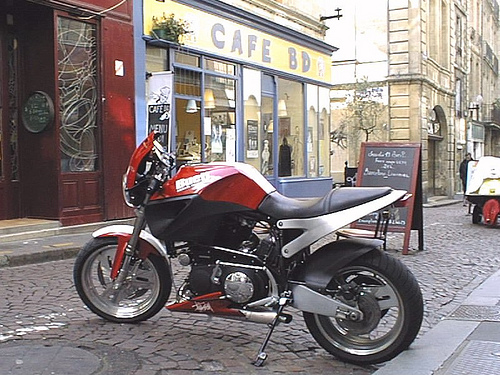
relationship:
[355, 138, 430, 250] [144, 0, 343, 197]
sign in front of cafe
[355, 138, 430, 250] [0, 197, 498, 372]
sign in middle of road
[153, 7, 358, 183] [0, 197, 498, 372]
cafe on side of road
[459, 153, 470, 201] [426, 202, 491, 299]
person walking down road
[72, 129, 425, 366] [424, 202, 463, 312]
motorcycle on street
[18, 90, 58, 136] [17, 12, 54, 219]
sign on wall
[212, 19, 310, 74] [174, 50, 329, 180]
restaurant`s name above glass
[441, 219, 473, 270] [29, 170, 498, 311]
cobblestone on street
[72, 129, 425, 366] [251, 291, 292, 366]
motorcycle on kick stand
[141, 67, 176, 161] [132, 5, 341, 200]
banner on wall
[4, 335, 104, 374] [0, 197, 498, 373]
manhole on road